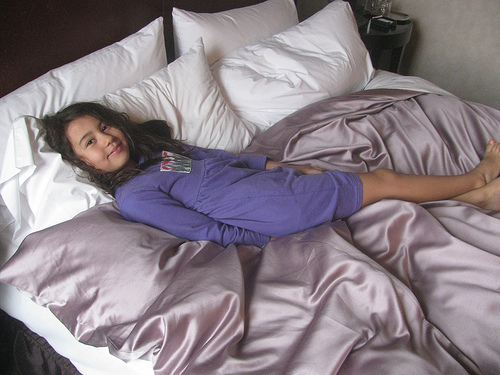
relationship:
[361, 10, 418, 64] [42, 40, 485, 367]
stand by bed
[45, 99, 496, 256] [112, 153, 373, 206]
girl with clothes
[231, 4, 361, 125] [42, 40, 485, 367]
pillow on bed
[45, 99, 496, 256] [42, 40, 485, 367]
girl on bed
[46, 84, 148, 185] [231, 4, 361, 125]
head on pillow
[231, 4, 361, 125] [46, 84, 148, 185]
pillow with head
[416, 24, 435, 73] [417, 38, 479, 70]
shadow on wall